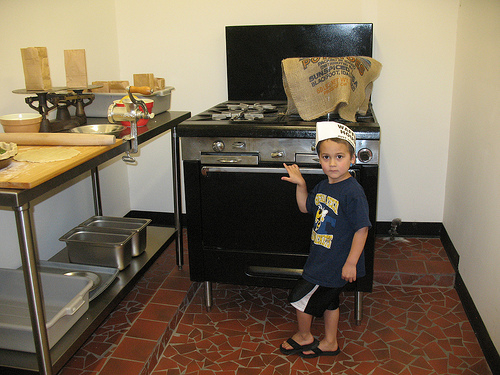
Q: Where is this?
A: This is at the kitchen.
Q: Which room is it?
A: It is a kitchen.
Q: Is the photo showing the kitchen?
A: Yes, it is showing the kitchen.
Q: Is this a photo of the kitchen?
A: Yes, it is showing the kitchen.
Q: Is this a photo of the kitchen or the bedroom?
A: It is showing the kitchen.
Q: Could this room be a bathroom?
A: No, it is a kitchen.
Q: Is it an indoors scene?
A: Yes, it is indoors.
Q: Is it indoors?
A: Yes, it is indoors.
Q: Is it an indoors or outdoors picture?
A: It is indoors.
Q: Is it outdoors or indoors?
A: It is indoors.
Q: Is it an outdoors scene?
A: No, it is indoors.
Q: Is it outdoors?
A: No, it is indoors.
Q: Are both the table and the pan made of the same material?
A: Yes, both the table and the pan are made of metal.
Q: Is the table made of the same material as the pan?
A: Yes, both the table and the pan are made of metal.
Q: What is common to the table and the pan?
A: The material, both the table and the pan are metallic.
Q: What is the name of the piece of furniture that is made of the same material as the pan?
A: The piece of furniture is a table.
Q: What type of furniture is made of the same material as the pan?
A: The table is made of the same material as the pan.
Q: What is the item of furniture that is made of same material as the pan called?
A: The piece of furniture is a table.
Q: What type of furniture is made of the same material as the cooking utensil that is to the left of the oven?
A: The table is made of the same material as the pan.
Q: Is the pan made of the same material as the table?
A: Yes, both the pan and the table are made of metal.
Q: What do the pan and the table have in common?
A: The material, both the pan and the table are metallic.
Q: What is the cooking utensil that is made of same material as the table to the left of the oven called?
A: The cooking utensil is a pan.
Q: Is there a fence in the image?
A: No, there are no fences.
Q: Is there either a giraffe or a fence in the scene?
A: No, there are no fences or giraffes.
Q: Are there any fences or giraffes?
A: No, there are no fences or giraffes.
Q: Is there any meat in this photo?
A: No, there is no meat.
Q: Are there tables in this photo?
A: Yes, there is a table.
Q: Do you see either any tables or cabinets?
A: Yes, there is a table.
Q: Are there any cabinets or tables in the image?
A: Yes, there is a table.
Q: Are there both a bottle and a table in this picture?
A: No, there is a table but no bottles.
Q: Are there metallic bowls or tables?
A: Yes, there is a metal table.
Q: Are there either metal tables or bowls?
A: Yes, there is a metal table.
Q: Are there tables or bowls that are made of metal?
A: Yes, the table is made of metal.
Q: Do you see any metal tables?
A: Yes, there is a metal table.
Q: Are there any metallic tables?
A: Yes, there is a metal table.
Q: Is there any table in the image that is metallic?
A: Yes, there is a table that is metallic.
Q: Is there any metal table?
A: Yes, there is a table that is made of metal.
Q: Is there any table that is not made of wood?
A: Yes, there is a table that is made of metal.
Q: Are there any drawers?
A: No, there are no drawers.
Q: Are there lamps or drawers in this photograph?
A: No, there are no drawers or lamps.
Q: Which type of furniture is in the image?
A: The furniture is a table.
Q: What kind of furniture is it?
A: The piece of furniture is a table.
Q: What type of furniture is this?
A: That is a table.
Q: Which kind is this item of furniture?
A: That is a table.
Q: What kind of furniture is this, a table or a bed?
A: That is a table.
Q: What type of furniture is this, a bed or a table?
A: That is a table.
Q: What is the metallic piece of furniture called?
A: The piece of furniture is a table.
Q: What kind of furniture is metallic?
A: The furniture is a table.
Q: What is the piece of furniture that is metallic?
A: The piece of furniture is a table.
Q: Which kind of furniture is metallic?
A: The furniture is a table.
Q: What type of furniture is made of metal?
A: The furniture is a table.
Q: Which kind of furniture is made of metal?
A: The furniture is a table.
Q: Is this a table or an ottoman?
A: This is a table.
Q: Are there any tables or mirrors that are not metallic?
A: No, there is a table but it is metallic.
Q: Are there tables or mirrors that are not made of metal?
A: No, there is a table but it is made of metal.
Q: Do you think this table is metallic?
A: Yes, the table is metallic.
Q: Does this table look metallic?
A: Yes, the table is metallic.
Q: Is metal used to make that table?
A: Yes, the table is made of metal.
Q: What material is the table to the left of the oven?
A: The table is made of metal.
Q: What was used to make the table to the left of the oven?
A: The table is made of metal.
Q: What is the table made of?
A: The table is made of metal.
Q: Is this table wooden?
A: No, the table is metallic.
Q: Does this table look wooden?
A: No, the table is metallic.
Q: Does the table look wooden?
A: No, the table is metallic.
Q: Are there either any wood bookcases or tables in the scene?
A: No, there is a table but it is metallic.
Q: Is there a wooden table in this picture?
A: No, there is a table but it is metallic.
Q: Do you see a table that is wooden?
A: No, there is a table but it is metallic.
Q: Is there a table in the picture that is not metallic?
A: No, there is a table but it is metallic.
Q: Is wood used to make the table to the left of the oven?
A: No, the table is made of metal.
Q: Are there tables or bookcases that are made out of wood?
A: No, there is a table but it is made of metal.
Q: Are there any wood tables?
A: No, there is a table but it is made of metal.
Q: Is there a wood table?
A: No, there is a table but it is made of metal.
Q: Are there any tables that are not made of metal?
A: No, there is a table but it is made of metal.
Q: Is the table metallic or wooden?
A: The table is metallic.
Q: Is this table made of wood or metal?
A: The table is made of metal.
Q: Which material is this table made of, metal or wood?
A: The table is made of metal.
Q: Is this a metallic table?
A: Yes, this is a metallic table.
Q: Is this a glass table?
A: No, this is a metallic table.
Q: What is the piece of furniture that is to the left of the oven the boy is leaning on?
A: The piece of furniture is a table.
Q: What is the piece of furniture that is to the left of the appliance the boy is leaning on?
A: The piece of furniture is a table.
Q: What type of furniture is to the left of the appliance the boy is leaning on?
A: The piece of furniture is a table.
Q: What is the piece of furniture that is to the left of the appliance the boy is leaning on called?
A: The piece of furniture is a table.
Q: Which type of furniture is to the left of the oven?
A: The piece of furniture is a table.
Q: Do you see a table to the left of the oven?
A: Yes, there is a table to the left of the oven.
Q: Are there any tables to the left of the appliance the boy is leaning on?
A: Yes, there is a table to the left of the oven.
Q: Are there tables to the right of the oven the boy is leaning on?
A: No, the table is to the left of the oven.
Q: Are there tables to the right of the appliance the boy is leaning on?
A: No, the table is to the left of the oven.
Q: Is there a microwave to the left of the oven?
A: No, there is a table to the left of the oven.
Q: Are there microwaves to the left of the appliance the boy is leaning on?
A: No, there is a table to the left of the oven.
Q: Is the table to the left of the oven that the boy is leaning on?
A: Yes, the table is to the left of the oven.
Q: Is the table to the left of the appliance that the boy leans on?
A: Yes, the table is to the left of the oven.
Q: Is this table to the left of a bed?
A: No, the table is to the left of the oven.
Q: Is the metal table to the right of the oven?
A: No, the table is to the left of the oven.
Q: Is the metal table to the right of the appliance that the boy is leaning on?
A: No, the table is to the left of the oven.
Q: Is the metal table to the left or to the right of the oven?
A: The table is to the left of the oven.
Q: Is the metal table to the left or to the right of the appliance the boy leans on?
A: The table is to the left of the oven.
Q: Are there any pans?
A: Yes, there is a pan.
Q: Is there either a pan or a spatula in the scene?
A: Yes, there is a pan.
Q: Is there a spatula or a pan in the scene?
A: Yes, there is a pan.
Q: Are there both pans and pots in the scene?
A: Yes, there are both a pan and a pot.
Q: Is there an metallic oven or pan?
A: Yes, there is a metal pan.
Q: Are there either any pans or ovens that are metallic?
A: Yes, the pan is metallic.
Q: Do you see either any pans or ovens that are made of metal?
A: Yes, the pan is made of metal.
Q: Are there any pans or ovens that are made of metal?
A: Yes, the pan is made of metal.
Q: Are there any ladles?
A: No, there are no ladles.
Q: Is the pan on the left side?
A: Yes, the pan is on the left of the image.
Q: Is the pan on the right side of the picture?
A: No, the pan is on the left of the image.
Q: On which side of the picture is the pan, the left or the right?
A: The pan is on the left of the image.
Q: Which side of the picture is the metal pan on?
A: The pan is on the left of the image.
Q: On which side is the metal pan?
A: The pan is on the left of the image.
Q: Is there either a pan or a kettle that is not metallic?
A: No, there is a pan but it is metallic.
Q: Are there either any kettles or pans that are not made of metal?
A: No, there is a pan but it is made of metal.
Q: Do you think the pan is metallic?
A: Yes, the pan is metallic.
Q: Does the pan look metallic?
A: Yes, the pan is metallic.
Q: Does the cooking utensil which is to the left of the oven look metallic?
A: Yes, the pan is metallic.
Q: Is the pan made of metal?
A: Yes, the pan is made of metal.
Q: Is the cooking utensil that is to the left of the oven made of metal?
A: Yes, the pan is made of metal.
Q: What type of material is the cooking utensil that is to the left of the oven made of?
A: The pan is made of metal.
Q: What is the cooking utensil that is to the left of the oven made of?
A: The pan is made of metal.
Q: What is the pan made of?
A: The pan is made of metal.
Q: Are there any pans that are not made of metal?
A: No, there is a pan but it is made of metal.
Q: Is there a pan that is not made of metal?
A: No, there is a pan but it is made of metal.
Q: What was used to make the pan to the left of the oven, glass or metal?
A: The pan is made of metal.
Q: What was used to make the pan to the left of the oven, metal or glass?
A: The pan is made of metal.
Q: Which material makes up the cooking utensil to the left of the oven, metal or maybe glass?
A: The pan is made of metal.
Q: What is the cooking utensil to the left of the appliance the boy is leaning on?
A: The cooking utensil is a pan.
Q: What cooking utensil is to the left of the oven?
A: The cooking utensil is a pan.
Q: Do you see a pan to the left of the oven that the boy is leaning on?
A: Yes, there is a pan to the left of the oven.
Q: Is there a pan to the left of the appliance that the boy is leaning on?
A: Yes, there is a pan to the left of the oven.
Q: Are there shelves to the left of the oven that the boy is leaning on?
A: No, there is a pan to the left of the oven.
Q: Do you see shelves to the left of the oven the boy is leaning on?
A: No, there is a pan to the left of the oven.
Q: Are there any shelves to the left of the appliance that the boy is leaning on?
A: No, there is a pan to the left of the oven.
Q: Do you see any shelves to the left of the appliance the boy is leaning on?
A: No, there is a pan to the left of the oven.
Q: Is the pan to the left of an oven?
A: Yes, the pan is to the left of an oven.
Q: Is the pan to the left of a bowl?
A: No, the pan is to the left of an oven.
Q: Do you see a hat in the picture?
A: Yes, there is a hat.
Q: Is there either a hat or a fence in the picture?
A: Yes, there is a hat.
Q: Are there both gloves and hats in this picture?
A: No, there is a hat but no gloves.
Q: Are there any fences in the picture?
A: No, there are no fences.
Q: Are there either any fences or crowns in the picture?
A: No, there are no fences or crowns.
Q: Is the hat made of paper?
A: Yes, the hat is made of paper.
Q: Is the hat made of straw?
A: No, the hat is made of paper.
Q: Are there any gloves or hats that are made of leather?
A: No, there is a hat but it is made of paper.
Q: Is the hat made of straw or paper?
A: The hat is made of paper.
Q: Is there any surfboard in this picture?
A: No, there are no surfboards.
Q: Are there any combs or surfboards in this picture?
A: No, there are no surfboards or combs.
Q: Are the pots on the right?
A: No, the pots are on the left of the image.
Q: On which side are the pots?
A: The pots are on the left of the image.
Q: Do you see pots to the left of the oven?
A: Yes, there are pots to the left of the oven.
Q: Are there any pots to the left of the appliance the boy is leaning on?
A: Yes, there are pots to the left of the oven.